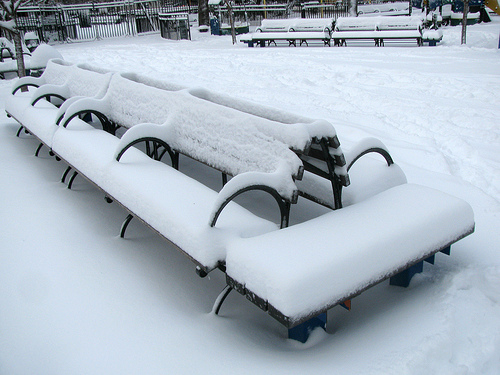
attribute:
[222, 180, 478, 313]
snow — white 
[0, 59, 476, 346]
bench — snow covered